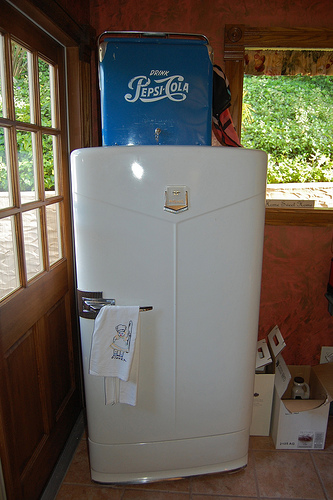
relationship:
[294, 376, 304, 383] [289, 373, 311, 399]
lid on bottle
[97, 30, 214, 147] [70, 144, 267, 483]
pepsi box on a fridge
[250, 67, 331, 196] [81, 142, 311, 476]
window behind fridge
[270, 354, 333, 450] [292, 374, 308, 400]
box with jug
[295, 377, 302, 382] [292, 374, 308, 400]
lid on jug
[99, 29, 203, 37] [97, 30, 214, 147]
silver handle on pepsi box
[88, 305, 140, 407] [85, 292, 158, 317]
dish towel on handle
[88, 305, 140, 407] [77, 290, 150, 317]
dish towel on door handle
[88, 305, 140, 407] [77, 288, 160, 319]
dish towel on door handle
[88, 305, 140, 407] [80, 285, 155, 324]
dish towel on handle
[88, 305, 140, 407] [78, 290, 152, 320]
dish towel on handle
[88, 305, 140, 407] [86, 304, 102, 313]
dish towel on door handle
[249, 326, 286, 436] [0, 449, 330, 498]
box on floor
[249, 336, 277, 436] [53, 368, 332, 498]
box on floor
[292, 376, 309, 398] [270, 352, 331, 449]
bottle on carton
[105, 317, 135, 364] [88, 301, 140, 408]
image on towel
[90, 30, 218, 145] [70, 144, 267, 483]
blue container on fridge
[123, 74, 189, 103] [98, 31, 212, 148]
pepsi cola on blue container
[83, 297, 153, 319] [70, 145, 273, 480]
door handle of refrigerator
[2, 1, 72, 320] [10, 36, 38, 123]
frame with glass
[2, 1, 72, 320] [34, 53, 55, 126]
frame with glass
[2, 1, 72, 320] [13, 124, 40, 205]
frame with glass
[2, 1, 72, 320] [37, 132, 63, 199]
frame with glass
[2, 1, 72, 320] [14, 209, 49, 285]
frame with glass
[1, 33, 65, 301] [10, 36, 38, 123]
window with glass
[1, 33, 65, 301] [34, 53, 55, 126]
window with glass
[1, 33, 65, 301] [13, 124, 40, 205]
window with glass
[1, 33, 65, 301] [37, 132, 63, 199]
window with glass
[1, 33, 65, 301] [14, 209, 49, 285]
window with glass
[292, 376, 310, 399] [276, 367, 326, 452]
bottle in box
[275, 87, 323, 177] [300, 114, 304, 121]
plants with leaf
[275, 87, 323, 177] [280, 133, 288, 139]
plants with leaf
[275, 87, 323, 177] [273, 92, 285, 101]
plants with leaf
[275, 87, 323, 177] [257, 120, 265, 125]
plants with leaf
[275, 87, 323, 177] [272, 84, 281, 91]
plants with leaf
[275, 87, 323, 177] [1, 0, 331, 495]
plants outside building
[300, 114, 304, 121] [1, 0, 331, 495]
leaf outside building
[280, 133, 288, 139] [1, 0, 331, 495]
leaf outside building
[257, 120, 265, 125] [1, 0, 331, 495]
leaf outside building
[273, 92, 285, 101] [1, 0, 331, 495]
leaf outside building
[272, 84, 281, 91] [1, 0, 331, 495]
leaf outside building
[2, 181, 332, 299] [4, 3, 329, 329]
sand outside building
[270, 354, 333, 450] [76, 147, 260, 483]
box near refrigerator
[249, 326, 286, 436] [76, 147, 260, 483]
box near refrigerator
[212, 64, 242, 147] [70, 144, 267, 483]
clothing on fridge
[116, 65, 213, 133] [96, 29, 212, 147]
logo on cooler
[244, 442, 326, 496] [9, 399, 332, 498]
tile on floor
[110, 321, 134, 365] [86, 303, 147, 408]
cartoon on dish towel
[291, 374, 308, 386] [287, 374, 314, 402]
cap on bottle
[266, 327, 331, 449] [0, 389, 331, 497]
box on floor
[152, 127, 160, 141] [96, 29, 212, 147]
spout on cooler